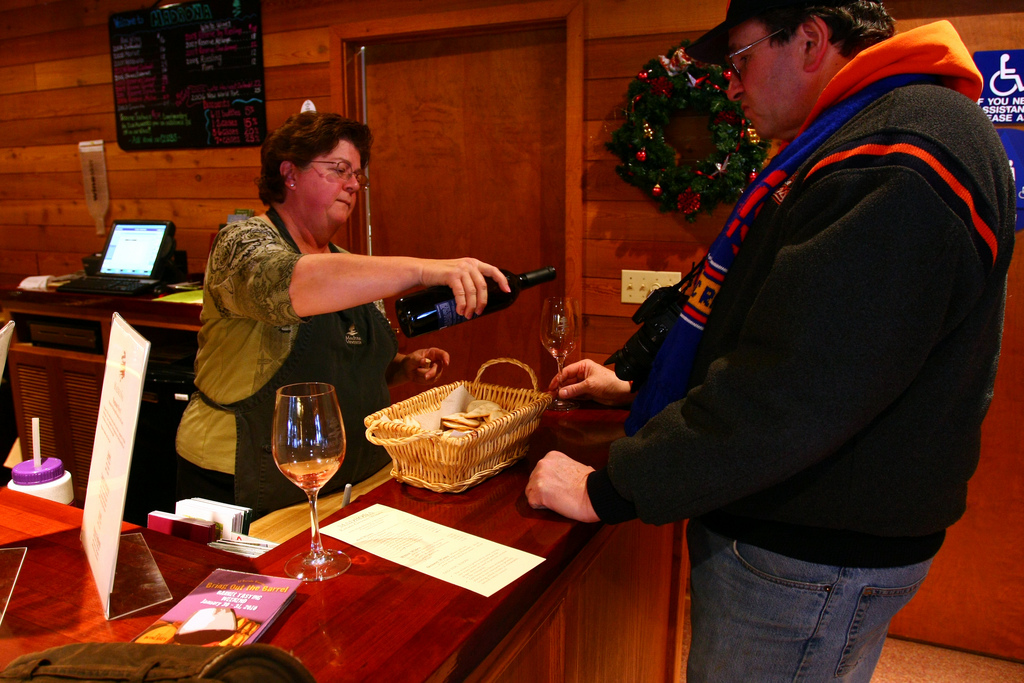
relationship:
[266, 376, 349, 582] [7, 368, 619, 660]
wine glass on counter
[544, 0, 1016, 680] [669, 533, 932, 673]
man wearing jeans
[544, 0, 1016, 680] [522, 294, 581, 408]
man holds glass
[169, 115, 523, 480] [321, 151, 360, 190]
woman wears glasses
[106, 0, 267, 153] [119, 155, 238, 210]
menu on wall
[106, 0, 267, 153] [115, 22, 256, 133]
menu with menu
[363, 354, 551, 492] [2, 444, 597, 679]
wick basket on counter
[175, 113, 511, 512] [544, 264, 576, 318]
woman pouring wine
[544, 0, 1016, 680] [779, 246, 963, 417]
man wearing black jacket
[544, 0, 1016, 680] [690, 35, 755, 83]
man wearing glasses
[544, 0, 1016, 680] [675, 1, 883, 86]
man wearing hat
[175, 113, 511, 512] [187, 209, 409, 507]
woman wearing apron